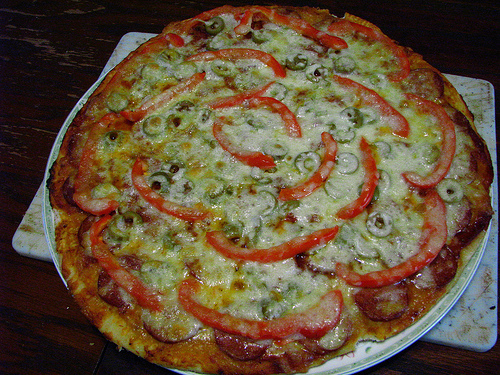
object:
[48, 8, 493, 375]
golden brown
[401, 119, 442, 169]
ground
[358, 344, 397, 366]
plate trim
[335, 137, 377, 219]
tomato slice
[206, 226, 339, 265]
tomato slice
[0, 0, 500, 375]
table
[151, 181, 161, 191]
black olive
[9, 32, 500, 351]
board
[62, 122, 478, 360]
pepperoni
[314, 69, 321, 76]
black olive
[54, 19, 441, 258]
black olive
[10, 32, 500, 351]
marble board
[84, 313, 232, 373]
crust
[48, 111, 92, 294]
crust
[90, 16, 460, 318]
olive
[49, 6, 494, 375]
pizza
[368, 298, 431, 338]
crust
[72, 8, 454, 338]
bell pepper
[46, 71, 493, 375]
plate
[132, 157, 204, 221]
tomato slice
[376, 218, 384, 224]
black olive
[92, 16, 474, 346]
cheese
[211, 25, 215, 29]
black olive